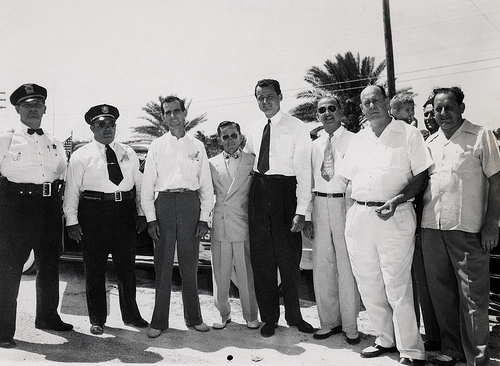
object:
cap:
[8, 82, 48, 105]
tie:
[104, 142, 126, 187]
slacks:
[247, 173, 306, 324]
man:
[241, 77, 315, 341]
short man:
[203, 115, 264, 330]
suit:
[207, 150, 259, 322]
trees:
[125, 94, 211, 142]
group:
[0, 81, 497, 366]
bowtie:
[27, 127, 44, 136]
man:
[0, 82, 74, 351]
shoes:
[86, 317, 108, 335]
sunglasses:
[94, 119, 116, 127]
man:
[59, 102, 148, 334]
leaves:
[305, 66, 330, 84]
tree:
[288, 52, 393, 129]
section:
[343, 77, 364, 91]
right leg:
[340, 198, 398, 345]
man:
[338, 84, 436, 366]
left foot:
[247, 315, 261, 329]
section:
[345, 218, 382, 289]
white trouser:
[340, 203, 430, 360]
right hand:
[146, 220, 164, 240]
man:
[138, 96, 217, 339]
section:
[317, 191, 343, 197]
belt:
[311, 191, 346, 199]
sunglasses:
[160, 109, 183, 114]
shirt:
[341, 118, 437, 200]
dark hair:
[160, 96, 186, 112]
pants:
[76, 188, 143, 327]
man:
[300, 96, 364, 346]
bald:
[360, 84, 384, 99]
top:
[322, 49, 375, 69]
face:
[222, 126, 240, 151]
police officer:
[62, 101, 152, 334]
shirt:
[0, 125, 69, 184]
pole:
[378, 0, 400, 98]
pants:
[308, 186, 364, 334]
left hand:
[194, 219, 211, 239]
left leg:
[176, 197, 204, 327]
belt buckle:
[326, 192, 334, 198]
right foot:
[144, 318, 170, 339]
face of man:
[97, 118, 116, 143]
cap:
[83, 104, 122, 121]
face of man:
[20, 97, 43, 123]